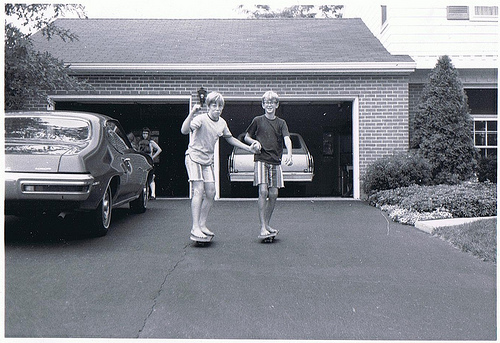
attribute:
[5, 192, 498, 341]
cement — black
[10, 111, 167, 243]
car — shiny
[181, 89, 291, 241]
boys — young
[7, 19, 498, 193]
house — white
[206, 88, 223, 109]
hair — blond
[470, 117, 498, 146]
window — bay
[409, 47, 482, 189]
tree — tall, well-groomed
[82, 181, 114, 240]
tire — rear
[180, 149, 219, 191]
shorts — striped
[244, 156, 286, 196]
shorts — striped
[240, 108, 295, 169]
tee shirt — dark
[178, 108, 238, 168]
tee shirt — dark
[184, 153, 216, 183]
shorts — short, striped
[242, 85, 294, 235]
boy — young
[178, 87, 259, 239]
boy — young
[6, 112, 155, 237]
sedan — shiny